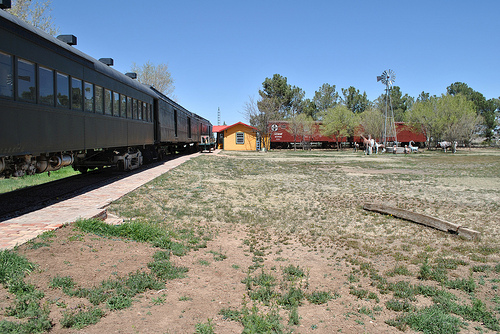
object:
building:
[209, 116, 269, 159]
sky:
[5, 0, 498, 122]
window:
[125, 97, 138, 120]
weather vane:
[374, 67, 400, 154]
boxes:
[46, 21, 127, 96]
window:
[93, 83, 111, 112]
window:
[15, 58, 40, 104]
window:
[56, 70, 70, 105]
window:
[81, 81, 95, 113]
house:
[212, 120, 270, 151]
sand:
[1, 139, 498, 332]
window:
[36, 65, 55, 104]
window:
[70, 75, 84, 110]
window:
[96, 84, 103, 114]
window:
[111, 92, 120, 118]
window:
[7, 48, 69, 163]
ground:
[186, 279, 251, 314]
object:
[360, 197, 485, 243]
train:
[0, 6, 217, 184]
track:
[0, 143, 187, 258]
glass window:
[108, 90, 132, 115]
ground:
[19, 147, 369, 330]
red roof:
[211, 123, 228, 130]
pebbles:
[340, 294, 391, 332]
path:
[0, 151, 202, 257]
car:
[2, 1, 157, 175]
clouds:
[88, 7, 265, 96]